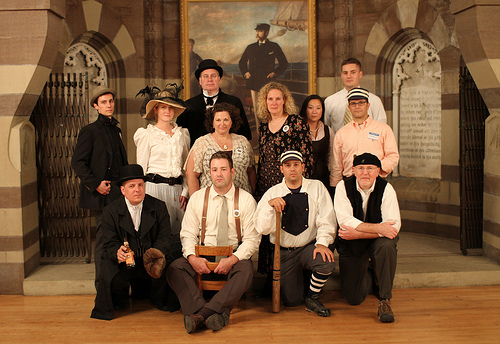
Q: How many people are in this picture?
A: 12.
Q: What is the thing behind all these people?
A: Portrait.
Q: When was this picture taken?
A: During the day.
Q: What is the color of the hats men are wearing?
A: Black.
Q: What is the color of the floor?
A: Brown.